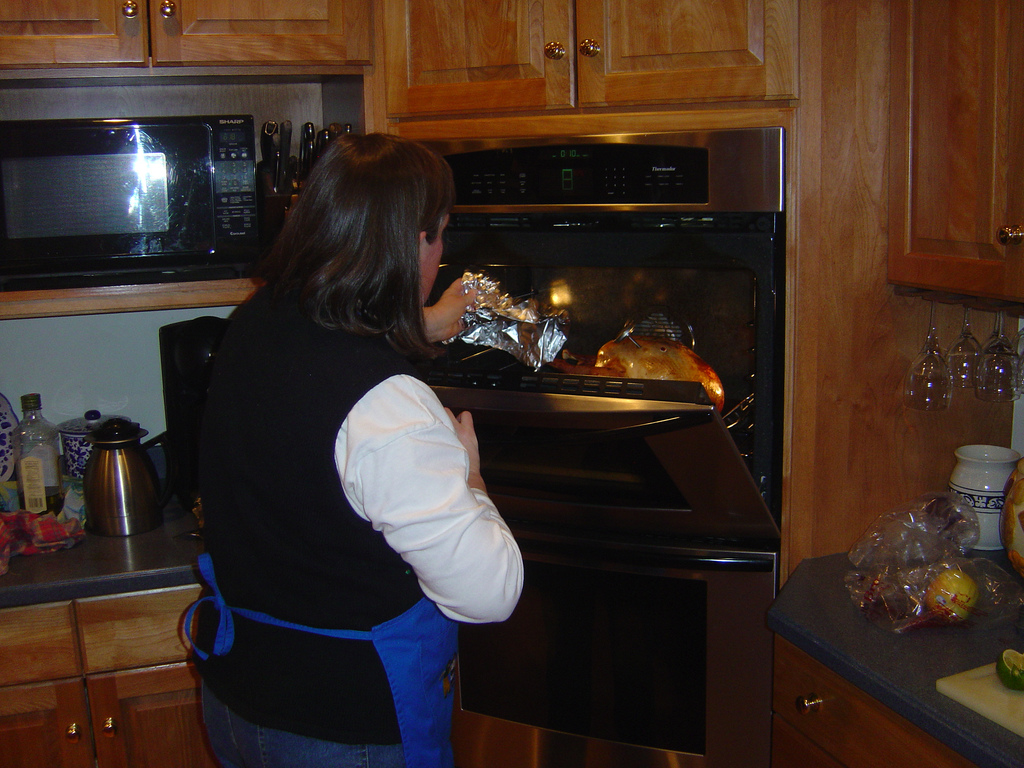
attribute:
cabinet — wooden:
[890, 0, 1021, 292]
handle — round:
[96, 711, 120, 743]